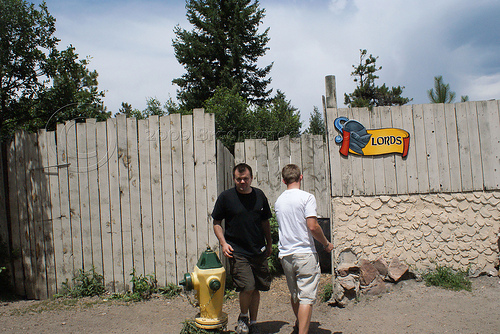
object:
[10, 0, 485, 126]
sky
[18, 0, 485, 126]
cloud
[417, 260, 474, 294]
grass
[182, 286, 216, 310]
chain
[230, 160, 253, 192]
head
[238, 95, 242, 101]
leaf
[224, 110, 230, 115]
leaf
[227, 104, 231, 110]
leaf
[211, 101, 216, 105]
leaf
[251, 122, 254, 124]
leaf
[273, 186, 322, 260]
shirt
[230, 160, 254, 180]
hair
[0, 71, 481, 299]
fence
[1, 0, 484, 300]
background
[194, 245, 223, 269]
top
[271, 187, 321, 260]
t-shirt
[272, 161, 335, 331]
man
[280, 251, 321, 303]
pants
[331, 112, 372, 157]
knight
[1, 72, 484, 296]
gate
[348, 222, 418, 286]
rocks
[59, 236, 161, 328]
bush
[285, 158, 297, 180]
hair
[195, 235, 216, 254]
cap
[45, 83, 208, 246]
fence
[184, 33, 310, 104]
pine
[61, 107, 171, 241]
fence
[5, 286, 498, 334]
ground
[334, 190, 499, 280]
wall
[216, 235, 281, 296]
shorts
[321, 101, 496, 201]
wall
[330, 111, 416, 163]
sign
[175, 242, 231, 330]
fire hydrant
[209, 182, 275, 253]
shirt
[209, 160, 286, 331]
man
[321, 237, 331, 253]
watch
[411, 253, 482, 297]
plant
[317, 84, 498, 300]
wall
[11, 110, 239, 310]
wall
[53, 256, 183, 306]
plant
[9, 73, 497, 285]
wall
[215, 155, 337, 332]
men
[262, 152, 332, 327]
guy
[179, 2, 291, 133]
leaves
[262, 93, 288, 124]
leaves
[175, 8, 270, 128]
leaves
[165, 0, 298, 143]
tree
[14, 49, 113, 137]
leaves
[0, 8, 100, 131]
tree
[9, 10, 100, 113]
leaves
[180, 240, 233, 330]
hydrant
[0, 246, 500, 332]
ground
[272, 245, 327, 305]
shorts